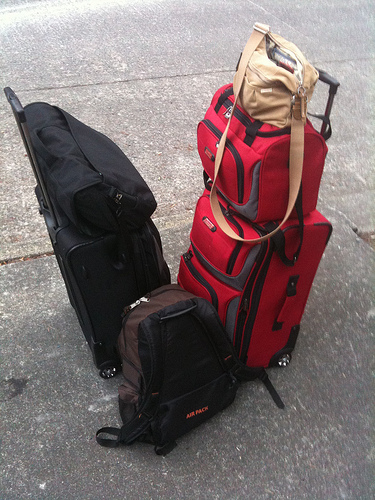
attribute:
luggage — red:
[178, 83, 334, 375]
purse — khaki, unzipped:
[209, 21, 320, 244]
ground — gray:
[0, 1, 373, 499]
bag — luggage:
[175, 184, 341, 388]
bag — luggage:
[187, 79, 337, 233]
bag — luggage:
[231, 16, 322, 130]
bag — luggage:
[116, 297, 226, 446]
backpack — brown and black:
[121, 307, 221, 451]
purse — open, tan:
[233, 34, 316, 142]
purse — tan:
[215, 25, 328, 127]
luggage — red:
[197, 99, 319, 389]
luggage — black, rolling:
[25, 128, 117, 385]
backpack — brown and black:
[120, 314, 237, 444]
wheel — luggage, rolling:
[276, 355, 295, 372]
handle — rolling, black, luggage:
[2, 85, 49, 183]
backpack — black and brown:
[85, 276, 245, 452]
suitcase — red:
[203, 130, 314, 363]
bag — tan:
[238, 42, 302, 136]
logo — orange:
[182, 400, 217, 422]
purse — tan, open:
[223, 20, 322, 126]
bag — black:
[45, 111, 145, 216]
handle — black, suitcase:
[4, 87, 46, 159]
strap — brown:
[203, 204, 261, 244]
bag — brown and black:
[135, 310, 235, 427]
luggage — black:
[27, 93, 144, 281]